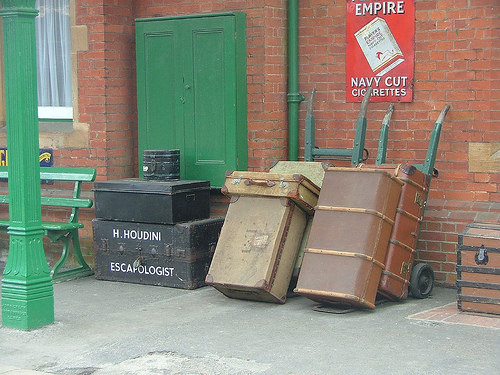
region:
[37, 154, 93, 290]
green bench by building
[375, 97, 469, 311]
green dolly holding cases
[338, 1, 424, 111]
sign on a building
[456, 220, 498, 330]
chest on the ground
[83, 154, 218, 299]
black cases on the ground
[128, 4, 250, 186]
green doors of a brick building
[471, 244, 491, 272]
lock on a chest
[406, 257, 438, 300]
wheel of a dolly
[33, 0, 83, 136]
window on a building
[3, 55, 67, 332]
green pole by the building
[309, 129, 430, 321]
Suit case on a hand truck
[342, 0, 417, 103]
red poster on a building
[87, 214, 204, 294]
black trunk on the ground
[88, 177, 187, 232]
Black shoe case against the wall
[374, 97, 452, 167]
green hand truck leaning against the wall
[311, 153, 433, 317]
two suit cases on the handtruck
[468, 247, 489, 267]
metal lock on the case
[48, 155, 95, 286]
Green bench near the cases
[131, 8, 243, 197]
Green cabinet on the wall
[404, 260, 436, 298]
black wheel on the handtruck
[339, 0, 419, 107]
an old advert for cigarettes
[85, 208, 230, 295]
Harry Houdini appears to have returned from the dead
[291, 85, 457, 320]
trunks heavy enough that the green carts are used to haul them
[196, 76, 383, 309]
a second stack of heavy luggage on a cart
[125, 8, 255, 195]
these doors do not extend to the ground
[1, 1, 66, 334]
an old-fashioned lamppost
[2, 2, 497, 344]
this looks like a movie set dressed for circa 1900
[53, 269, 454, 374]
concrete sidewalk outside this building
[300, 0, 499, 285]
the wall is made of brick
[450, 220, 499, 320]
a steamer trunk off to the right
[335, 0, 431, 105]
red cigarette sign on wall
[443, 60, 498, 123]
red brick wall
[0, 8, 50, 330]
tall pole painted green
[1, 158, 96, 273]
metal bench painted green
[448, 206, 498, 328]
wooden trunk with black metal bands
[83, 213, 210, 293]
black trunk with white lettering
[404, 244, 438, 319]
black wheel on hand cart.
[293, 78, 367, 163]
green handles of hand cart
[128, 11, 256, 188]
green cabinet hung on wall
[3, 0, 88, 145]
window with white curtains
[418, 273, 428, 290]
part of a wheel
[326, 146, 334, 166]
edge of a pole